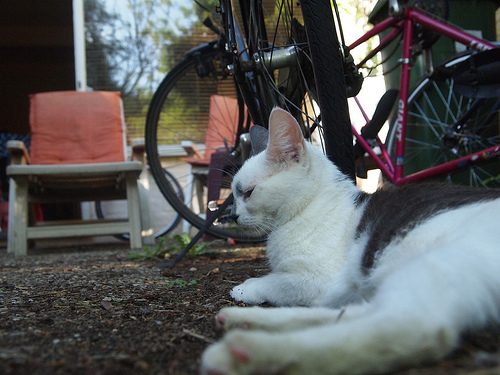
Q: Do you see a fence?
A: No, there are no fences.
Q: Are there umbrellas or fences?
A: No, there are no fences or umbrellas.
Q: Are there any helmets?
A: No, there are no helmets.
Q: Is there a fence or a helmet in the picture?
A: No, there are no helmets or fences.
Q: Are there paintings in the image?
A: No, there are no paintings.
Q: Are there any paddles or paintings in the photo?
A: No, there are no paintings or paddles.